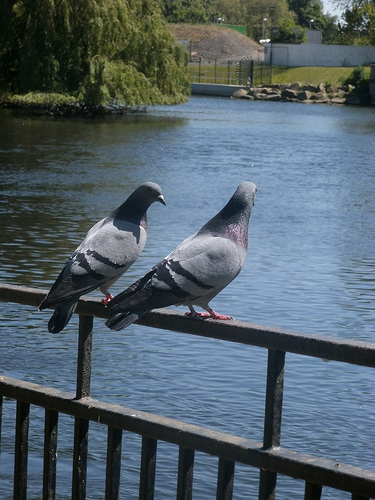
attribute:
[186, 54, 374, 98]
hill — grassy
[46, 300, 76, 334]
tail feather — gray, dark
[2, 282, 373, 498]
railing — metal , gray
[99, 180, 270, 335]
pigeon — gray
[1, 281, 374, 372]
railing — black metal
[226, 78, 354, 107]
rock pile — large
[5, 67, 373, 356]
lake — blue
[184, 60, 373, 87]
hill — grassy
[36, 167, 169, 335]
red foot — red 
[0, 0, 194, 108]
trees — green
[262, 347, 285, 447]
bar — black vertical 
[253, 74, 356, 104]
gray pile — light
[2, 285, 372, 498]
rail — left black horizontal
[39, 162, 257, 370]
pigeons — under 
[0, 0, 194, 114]
tree — green 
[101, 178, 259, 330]
pigeon — under 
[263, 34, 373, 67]
building — white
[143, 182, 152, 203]
eye — beady, black